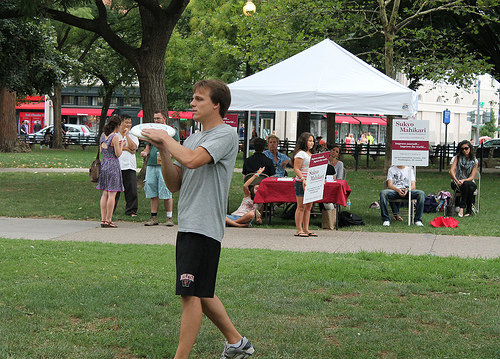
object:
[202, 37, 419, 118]
tent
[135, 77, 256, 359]
man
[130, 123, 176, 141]
frisbee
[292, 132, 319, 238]
girl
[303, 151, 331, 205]
sign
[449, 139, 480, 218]
woman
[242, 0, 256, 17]
light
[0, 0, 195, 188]
trees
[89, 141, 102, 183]
purse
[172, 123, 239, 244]
shirt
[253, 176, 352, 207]
table cloth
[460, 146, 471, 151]
sunglasses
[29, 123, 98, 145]
car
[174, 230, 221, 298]
shorts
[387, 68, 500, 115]
sky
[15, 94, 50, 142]
shops